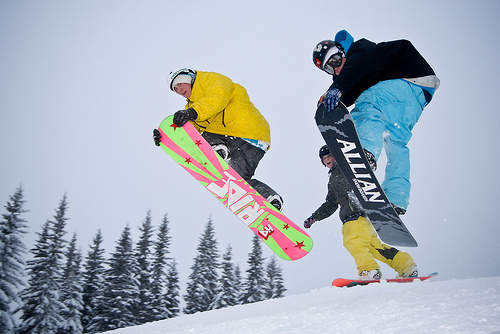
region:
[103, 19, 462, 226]
snowboarders in the photo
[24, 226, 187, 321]
trees in the distance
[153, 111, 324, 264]
board under the person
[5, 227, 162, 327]
snow on the trees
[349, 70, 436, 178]
blue pants on person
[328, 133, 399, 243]
writing on the board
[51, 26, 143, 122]
sky above the land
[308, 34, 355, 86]
goggles on the person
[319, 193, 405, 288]
yellow pants on the person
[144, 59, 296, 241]
man on snowboard in air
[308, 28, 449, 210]
man on snowboard in air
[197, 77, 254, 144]
man wearing yellow jacket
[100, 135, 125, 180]
white clouds in blue sky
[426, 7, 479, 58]
white clouds in blue sky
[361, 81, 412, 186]
man with blue pants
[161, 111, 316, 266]
The pink and green snowboard.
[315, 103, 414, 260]
The black and white snowboard.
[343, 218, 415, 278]
The yellow pants the guy is wearing.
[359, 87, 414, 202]
The blue pants the guy is wearing.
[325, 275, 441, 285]
The orange snowboard.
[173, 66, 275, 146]
The yellow coat the man is wearing.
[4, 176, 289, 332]
The trees in the background.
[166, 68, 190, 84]
The white helmet the guy is wearing.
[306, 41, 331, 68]
The black helmet with colorful stickers on the guy's head.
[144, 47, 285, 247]
snow boarder in air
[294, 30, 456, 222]
snow boarder in air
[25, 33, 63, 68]
white clouds in blue sky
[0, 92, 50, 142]
white clouds in blue sky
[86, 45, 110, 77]
white clouds in blue sky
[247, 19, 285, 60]
white clouds in blue sky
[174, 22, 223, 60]
white clouds in blue sky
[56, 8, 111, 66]
white clouds in blue sky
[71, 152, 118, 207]
white clouds in blue sky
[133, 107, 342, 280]
a pink and green snowboard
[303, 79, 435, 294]
a blue and white snowboard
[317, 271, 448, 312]
a orange snowboard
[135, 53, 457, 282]
three people snowboarding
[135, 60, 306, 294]
a person snowboarding in the air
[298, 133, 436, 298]
a person snowboarding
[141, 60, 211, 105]
a person wearing a white helmet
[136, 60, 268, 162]
a person wearing a yellow jacket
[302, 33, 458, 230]
a person wearing blue ski pants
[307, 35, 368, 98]
a person wearing goggles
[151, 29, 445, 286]
three people are snowboarding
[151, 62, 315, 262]
person wearing yellow jacket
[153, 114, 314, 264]
pink, green and white snowboard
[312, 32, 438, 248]
snowboarder wearing black goggles